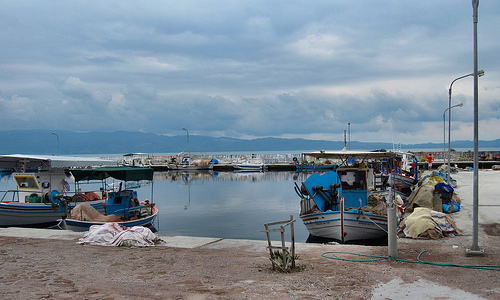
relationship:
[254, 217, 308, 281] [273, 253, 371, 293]
strick in ground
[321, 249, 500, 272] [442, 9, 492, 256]
hose near pole